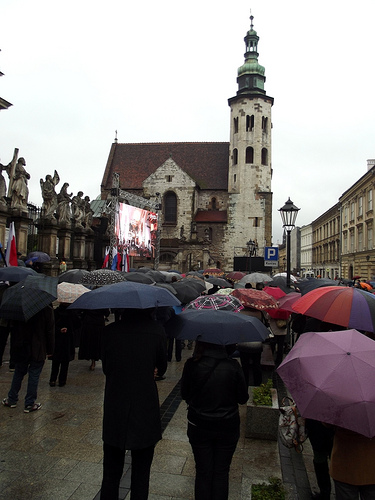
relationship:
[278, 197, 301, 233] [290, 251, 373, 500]
lamp on street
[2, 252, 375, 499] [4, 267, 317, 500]
people standing on sidewalk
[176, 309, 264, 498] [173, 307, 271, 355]
person holding an umbrella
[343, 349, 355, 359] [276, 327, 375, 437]
circle on top of umbrella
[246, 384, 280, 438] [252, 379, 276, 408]
planter holding plant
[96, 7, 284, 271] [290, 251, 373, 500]
building on side of street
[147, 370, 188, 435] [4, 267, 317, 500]
tiles on sidewalk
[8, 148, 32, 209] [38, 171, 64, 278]
statue on top of statue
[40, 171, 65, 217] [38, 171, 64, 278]
statue on top of statue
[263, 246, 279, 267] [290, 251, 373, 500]
sign beside street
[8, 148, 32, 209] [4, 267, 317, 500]
statue beside sidewalk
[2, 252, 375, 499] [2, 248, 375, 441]
people are holding umbrellas